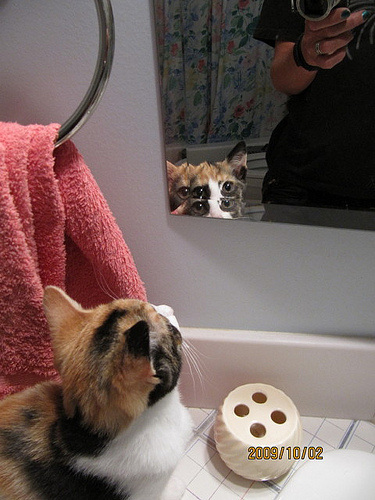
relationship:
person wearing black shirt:
[272, 8, 362, 92] [262, 70, 373, 208]